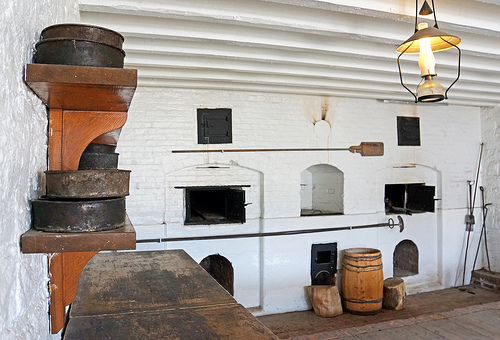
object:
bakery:
[0, 2, 499, 338]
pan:
[43, 168, 132, 199]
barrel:
[341, 247, 384, 314]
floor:
[251, 281, 499, 339]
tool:
[171, 142, 385, 157]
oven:
[182, 187, 246, 227]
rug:
[285, 299, 499, 339]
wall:
[114, 89, 500, 319]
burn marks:
[319, 95, 331, 120]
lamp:
[394, 2, 462, 103]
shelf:
[20, 208, 137, 256]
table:
[61, 248, 281, 339]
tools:
[459, 203, 494, 296]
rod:
[133, 214, 403, 244]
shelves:
[22, 61, 138, 113]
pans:
[26, 196, 127, 235]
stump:
[383, 276, 408, 310]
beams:
[254, 0, 500, 41]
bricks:
[293, 312, 316, 327]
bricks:
[232, 123, 260, 130]